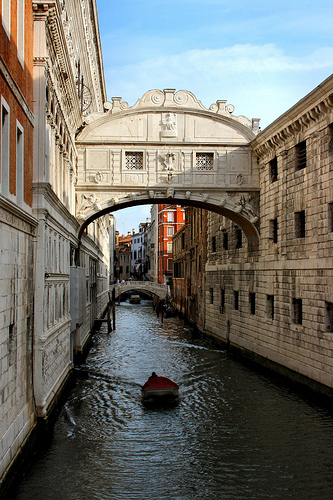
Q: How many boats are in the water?
A: One.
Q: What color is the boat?
A: Red.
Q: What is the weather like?
A: Sunny.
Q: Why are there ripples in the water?
A: The boat is moving.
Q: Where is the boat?
A: In the water.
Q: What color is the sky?
A: Blue.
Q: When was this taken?
A: During the day.